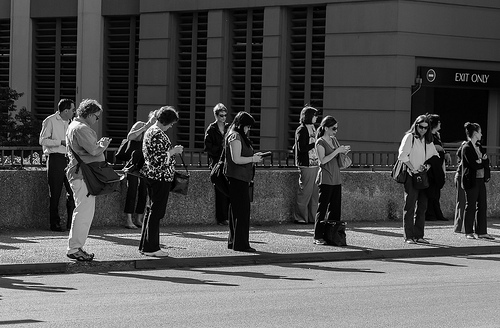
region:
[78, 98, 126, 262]
woman standing by sidewalk in black and white photo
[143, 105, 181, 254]
woman standing by sidewalk in black and white photo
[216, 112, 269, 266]
woman standing by sidewalk in black and white photo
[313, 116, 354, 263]
woman standing by sidewalk in black and white photo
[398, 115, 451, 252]
woman standing by sidewalk in black and white photo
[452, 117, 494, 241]
woman standing by sidewalk in black and white photo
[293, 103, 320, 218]
woman standing by sidewalk in black and white photo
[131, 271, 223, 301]
shadow of woman standing by sidewalk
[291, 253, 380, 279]
shadow of woman standing by sidewalk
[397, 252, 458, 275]
shadow of woman standing by sidewalk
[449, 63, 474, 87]
this is the white word exit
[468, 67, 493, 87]
this is the word only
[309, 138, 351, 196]
this is a gray shirt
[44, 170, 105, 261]
these are white pants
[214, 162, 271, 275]
these are black pants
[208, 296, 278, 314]
this is the concrete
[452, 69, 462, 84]
this is the letter E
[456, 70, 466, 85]
this is the letter X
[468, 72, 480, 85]
this is the letter O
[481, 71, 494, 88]
this is the letter Y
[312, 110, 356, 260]
young woman wearing sunglasses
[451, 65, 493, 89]
sign that reads exit only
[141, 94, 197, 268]
woman holding black purse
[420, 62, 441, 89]
circle with single dash in middle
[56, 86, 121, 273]
man wearing white pants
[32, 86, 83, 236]
man in white shirt looking to his left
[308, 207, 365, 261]
black bag between persons feet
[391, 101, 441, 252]
woman reaching into purse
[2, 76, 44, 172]
small trees in front of building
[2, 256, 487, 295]
shadows of people cast onto street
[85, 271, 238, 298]
shadow in the street of a woman standing on the sidewalk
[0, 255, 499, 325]
city street in front of the sidewalk where the people are standing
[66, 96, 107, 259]
woman in light colored pants standing and texting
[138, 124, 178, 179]
patterned shirt worn by a woman standing and texting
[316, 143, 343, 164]
bare right arm of a woman standing and texting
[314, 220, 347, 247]
bag on the sidewalk at a woman's feet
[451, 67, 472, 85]
exit in capital letters in the window of a building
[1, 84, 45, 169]
bush behind the cement wall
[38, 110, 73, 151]
white shirt on a man standing on the sidewalk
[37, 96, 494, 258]
group of people standing on a city sidewalk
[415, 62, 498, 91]
an exit sign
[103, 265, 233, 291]
the shadow of a person on the road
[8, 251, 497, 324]
a paved road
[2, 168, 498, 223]
a short concrete wall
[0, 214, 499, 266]
a sidewalk full of people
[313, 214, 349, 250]
a bag at a woman's feet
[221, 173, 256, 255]
black pants on a woman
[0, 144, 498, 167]
a railing on top of a wall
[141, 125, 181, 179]
a print shirt on a woman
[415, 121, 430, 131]
sunglasses on a person